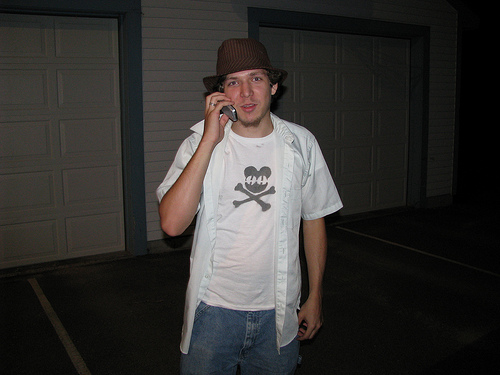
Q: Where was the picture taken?
A: In front a house.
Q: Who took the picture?
A: The man's girlfriend.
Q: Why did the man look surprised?
A: He was talking to someone other than girlfriend.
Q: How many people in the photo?
A: One.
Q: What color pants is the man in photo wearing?
A: Blue.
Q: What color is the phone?
A: Silver.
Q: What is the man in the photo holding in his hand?
A: A phone.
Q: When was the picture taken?
A: At night.